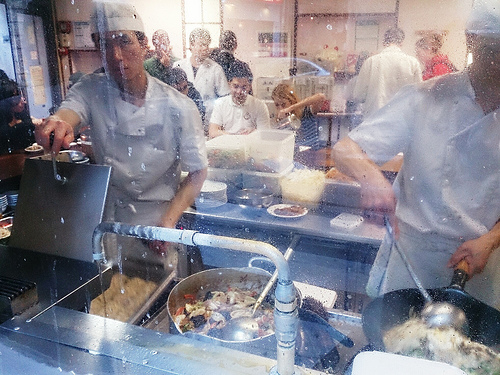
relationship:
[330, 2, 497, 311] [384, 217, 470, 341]
man holding spoon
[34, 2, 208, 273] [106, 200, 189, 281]
man in apron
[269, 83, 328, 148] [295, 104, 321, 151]
woman has shirt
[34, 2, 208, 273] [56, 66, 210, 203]
man in shirt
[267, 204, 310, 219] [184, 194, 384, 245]
plate on counter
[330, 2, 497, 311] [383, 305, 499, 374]
man serving food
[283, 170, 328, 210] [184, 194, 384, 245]
food on counter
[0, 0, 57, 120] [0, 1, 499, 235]
doorway to restaurant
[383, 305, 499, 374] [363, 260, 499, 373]
food in pan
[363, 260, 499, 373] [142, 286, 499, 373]
pan on cooker